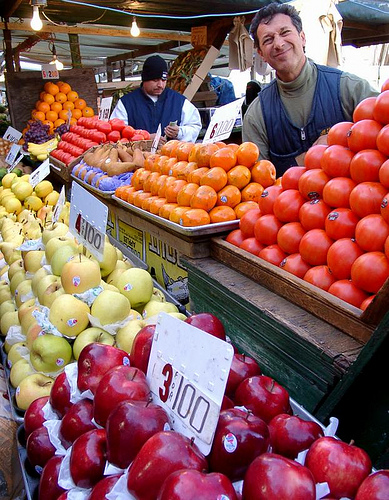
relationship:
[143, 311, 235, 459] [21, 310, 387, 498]
sign in apples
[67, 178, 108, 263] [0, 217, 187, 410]
sign on apples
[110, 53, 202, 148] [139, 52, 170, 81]
man with hat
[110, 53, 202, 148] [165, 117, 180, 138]
man handling money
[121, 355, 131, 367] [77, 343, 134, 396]
sticker on apple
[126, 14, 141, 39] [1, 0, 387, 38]
light bulb hanging from ceiling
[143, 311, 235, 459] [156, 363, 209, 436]
sign has writing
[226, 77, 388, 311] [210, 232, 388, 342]
tomatoes stacked in case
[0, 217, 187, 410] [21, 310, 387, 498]
apples next to apples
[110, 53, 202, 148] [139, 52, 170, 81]
man wearing hat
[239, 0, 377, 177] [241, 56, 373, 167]
man in shirt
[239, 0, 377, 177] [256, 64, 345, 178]
man in vest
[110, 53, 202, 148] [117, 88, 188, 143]
man wearing vest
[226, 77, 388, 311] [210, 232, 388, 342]
tomatoes in case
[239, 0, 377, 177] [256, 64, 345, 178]
man wearing vest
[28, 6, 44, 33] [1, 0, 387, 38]
light bulb hanging from ceiling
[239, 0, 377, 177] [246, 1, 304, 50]
man with hair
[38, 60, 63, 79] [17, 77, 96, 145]
sign above oranges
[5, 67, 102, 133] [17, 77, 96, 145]
board behind oranges